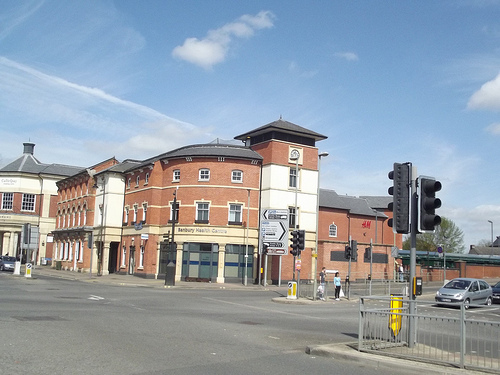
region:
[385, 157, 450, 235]
Stop lights on the street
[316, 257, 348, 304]
Man and woman standing waiting for the go signal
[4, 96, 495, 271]
old brick building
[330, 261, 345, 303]
lady in blue shirt holding a white plastic bag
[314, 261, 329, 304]
man standing holding a plastic bag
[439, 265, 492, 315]
gray car on stop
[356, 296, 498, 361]
gray fence near the signal sign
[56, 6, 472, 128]
clouded blue sky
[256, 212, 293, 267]
gray direction sign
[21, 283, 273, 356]
concrete road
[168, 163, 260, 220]
The building has windows.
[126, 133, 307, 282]
The building is made of bricks.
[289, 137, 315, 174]
A clock sits on top of the building.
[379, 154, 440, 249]
Traffic lights on the street.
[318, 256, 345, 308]
People waiting to cross the street.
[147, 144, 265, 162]
The roof is black.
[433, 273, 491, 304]
A silver car on the corner.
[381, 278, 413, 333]
A yellow sign posted on the gate.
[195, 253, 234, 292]
The door of the building.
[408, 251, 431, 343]
The pole is iron.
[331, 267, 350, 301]
Woman with blue shirt and black pants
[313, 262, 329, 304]
Man in grey shirt with large bag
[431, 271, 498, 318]
Silver car on side street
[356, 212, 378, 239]
Red H&M sign on building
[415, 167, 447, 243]
Three section traffic signal on right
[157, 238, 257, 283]
White windows with blue stripe on curved part of building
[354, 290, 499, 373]
Silver railing in street below traffic signal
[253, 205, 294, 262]
Large directional sign in front of building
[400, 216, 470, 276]
Green tree branches behind building on right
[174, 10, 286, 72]
Fluffy cloud in middle of sky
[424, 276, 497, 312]
Small silver car on road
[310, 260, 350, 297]
Man and small woman stand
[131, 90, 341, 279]
Large brick building by road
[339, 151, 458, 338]
Traffic lights and yellow sign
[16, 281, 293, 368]
Paved street is clean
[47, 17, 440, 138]
Clear blue sky today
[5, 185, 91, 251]
Buildings with lots of windows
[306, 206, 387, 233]
Brick building with red lettering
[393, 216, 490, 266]
2 trees that are tall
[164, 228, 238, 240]
Words on building unreadable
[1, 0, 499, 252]
The sky is blue and lightly cloudy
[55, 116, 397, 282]
Building in center is mainly made of bricks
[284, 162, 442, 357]
Stop lights are on each meridian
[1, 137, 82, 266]
building in background has curved entry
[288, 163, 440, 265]
stop light casing is black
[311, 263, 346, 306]
people wait for their turn on the meridian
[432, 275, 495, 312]
silver car on right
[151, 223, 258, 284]
closest building is a health center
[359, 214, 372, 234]
Red letters are on side of building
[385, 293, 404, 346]
yellow sign in front of stoplight